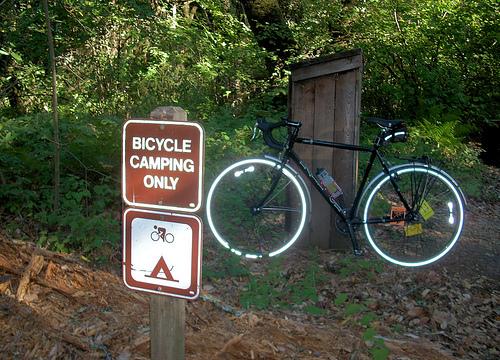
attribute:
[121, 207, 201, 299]
warning sign — red, white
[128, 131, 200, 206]
letters — white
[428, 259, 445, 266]
tire — back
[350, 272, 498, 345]
dead leaves — brown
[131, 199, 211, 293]
sign — white, trimmed, tred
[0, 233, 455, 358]
wooded ground — wooden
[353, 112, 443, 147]
seat — black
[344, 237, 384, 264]
peddle — part 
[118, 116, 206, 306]
sign — street 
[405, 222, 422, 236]
card — yellow, orange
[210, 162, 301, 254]
spokes — metal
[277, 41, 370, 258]
barn — small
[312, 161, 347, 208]
bottle — water 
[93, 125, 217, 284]
sign — bicycle camping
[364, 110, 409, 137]
seat edge — edge 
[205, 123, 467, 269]
bike — black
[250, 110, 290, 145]
handle bars — curved, black